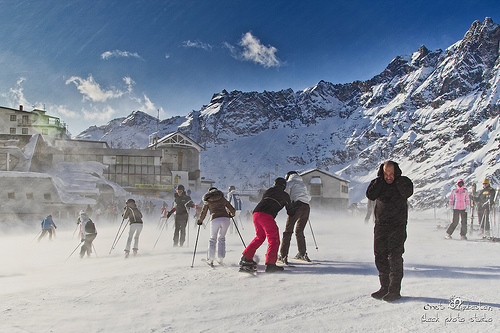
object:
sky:
[2, 1, 498, 135]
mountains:
[74, 14, 500, 212]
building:
[144, 131, 207, 193]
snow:
[0, 208, 500, 332]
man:
[365, 160, 414, 301]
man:
[238, 177, 301, 274]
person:
[468, 179, 496, 237]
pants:
[241, 211, 280, 264]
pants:
[206, 217, 230, 260]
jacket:
[449, 179, 471, 212]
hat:
[482, 178, 489, 184]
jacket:
[197, 189, 236, 223]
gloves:
[393, 162, 402, 180]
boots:
[382, 293, 402, 301]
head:
[456, 179, 464, 188]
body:
[444, 178, 470, 242]